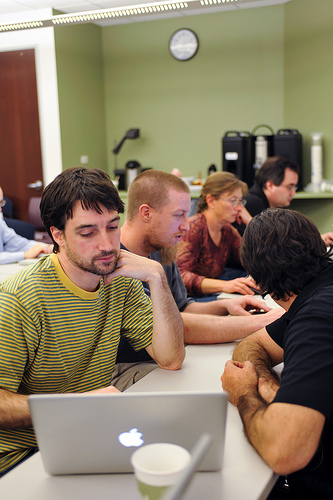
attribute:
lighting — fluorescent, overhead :
[1, 3, 269, 32]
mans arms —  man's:
[219, 325, 326, 475]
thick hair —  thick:
[237, 392, 262, 417]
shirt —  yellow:
[2, 254, 159, 473]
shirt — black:
[265, 261, 331, 499]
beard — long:
[158, 241, 180, 265]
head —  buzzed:
[126, 168, 189, 249]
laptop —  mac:
[24, 388, 230, 479]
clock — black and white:
[139, 23, 215, 70]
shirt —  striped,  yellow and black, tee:
[8, 262, 197, 424]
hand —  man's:
[103, 247, 168, 285]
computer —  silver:
[20, 387, 231, 489]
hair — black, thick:
[233, 337, 280, 390]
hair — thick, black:
[236, 389, 271, 437]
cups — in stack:
[299, 131, 332, 194]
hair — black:
[261, 158, 282, 176]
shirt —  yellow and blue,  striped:
[6, 253, 128, 390]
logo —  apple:
[112, 420, 148, 455]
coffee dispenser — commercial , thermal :
[265, 127, 308, 192]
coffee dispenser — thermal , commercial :
[219, 130, 250, 180]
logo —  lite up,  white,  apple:
[116, 425, 144, 450]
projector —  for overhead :
[110, 127, 142, 156]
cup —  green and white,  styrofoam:
[122, 419, 203, 498]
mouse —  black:
[233, 286, 262, 295]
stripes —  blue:
[47, 317, 88, 323]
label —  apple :
[118, 426, 142, 447]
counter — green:
[105, 174, 331, 212]